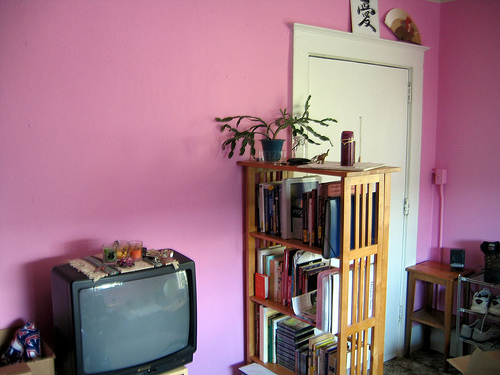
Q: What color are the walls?
A: Purple.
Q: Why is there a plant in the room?
A: It is there for decoration.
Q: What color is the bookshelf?
A: Brown.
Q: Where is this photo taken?
A: In a bedroom.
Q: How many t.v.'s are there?
A: One.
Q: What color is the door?
A: White.